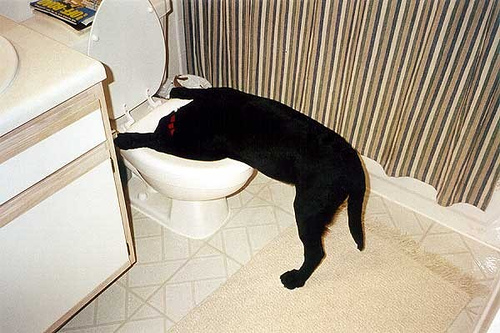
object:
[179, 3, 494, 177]
curtain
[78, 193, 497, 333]
floor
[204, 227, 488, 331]
mat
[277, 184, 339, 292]
leg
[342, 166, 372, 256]
tail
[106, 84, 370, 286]
dog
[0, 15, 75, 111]
sink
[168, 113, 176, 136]
collar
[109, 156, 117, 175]
hinges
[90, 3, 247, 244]
toilet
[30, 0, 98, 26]
magazines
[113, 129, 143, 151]
paw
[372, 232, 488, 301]
frills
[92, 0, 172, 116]
lid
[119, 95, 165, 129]
hinges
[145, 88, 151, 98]
screws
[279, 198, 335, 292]
hind leg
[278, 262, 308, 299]
back paw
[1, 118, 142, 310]
cabinet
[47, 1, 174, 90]
tank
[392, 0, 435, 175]
stripes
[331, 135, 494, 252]
bathtub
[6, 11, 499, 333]
bathroom